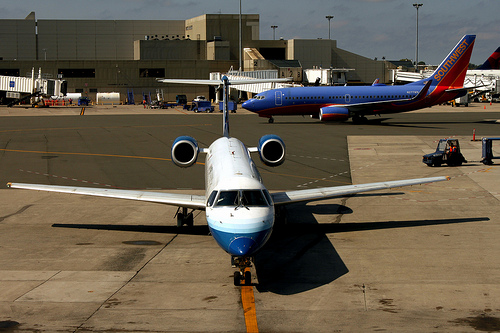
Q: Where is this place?
A: Airport.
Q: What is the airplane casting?
A: Shadow.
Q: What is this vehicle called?
A: Airplane.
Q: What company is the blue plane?
A: Southwest.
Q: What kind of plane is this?
A: Passenger.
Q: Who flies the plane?
A: Pilot.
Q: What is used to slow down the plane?
A: Tires.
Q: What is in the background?
A: Airport terminal.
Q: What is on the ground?
A: Planes.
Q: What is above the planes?
A: The sky.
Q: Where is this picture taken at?
A: Airport.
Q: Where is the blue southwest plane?
A: In the back.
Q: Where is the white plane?
A: In front.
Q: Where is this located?
A: Airport.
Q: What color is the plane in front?
A: White.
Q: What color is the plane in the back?
A: Blue.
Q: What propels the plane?
A: Engine.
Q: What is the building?
A: Airport terminal.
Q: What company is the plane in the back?
A: Southwest.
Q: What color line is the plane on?
A: Yellow.